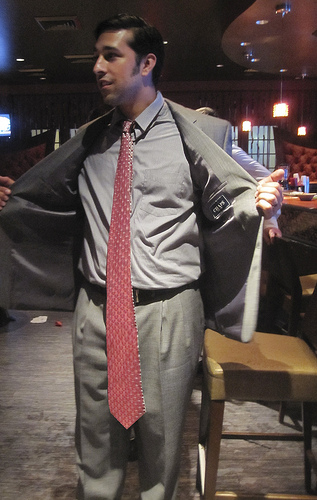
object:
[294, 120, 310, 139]
light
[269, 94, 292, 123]
light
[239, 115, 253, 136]
light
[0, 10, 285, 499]
man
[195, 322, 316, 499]
stool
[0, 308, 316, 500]
floor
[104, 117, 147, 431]
necktie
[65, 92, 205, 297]
shirt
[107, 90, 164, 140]
collar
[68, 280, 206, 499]
pants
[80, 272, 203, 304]
belt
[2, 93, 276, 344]
jacket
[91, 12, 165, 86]
hair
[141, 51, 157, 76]
ear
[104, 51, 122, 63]
eye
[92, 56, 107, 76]
nose